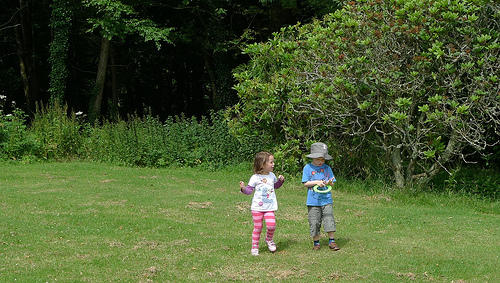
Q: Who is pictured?
A: Two children.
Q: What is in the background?
A: Grass, trees and foliage.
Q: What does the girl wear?
A: Pink striped leggings.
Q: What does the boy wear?
A: A hat.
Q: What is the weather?
A: Sunny and warm.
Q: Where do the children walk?
A: On the green grass.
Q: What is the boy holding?
A: A green toy.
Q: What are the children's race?
A: Caucasian.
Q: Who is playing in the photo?
A: Children.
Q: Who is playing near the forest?
A: Two children.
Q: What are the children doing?
A: Standing.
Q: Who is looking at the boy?
A: The girl.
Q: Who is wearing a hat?
A: The boy.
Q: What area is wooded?
A: The background.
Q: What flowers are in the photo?
A: White ones.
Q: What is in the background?
A: Forest.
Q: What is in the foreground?
A: Grass.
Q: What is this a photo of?
A: 2 children walking.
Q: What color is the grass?
A: Green.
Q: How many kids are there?
A: Two.